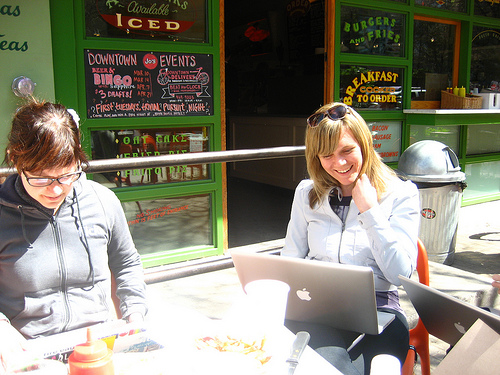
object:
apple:
[296, 288, 312, 301]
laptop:
[231, 253, 396, 335]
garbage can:
[393, 140, 466, 266]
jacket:
[280, 179, 420, 292]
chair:
[401, 237, 429, 375]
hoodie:
[0, 171, 148, 340]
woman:
[0, 90, 147, 375]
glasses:
[20, 158, 83, 186]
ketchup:
[67, 354, 115, 375]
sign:
[87, 50, 211, 119]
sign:
[345, 17, 400, 44]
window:
[334, 0, 500, 208]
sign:
[343, 71, 398, 106]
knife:
[285, 330, 311, 374]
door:
[219, 1, 334, 251]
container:
[245, 279, 290, 333]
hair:
[0, 88, 90, 175]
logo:
[296, 288, 311, 302]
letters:
[392, 73, 399, 83]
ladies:
[279, 102, 420, 375]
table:
[0, 288, 345, 375]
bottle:
[67, 328, 113, 374]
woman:
[280, 102, 420, 375]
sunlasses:
[304, 104, 359, 124]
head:
[306, 102, 385, 209]